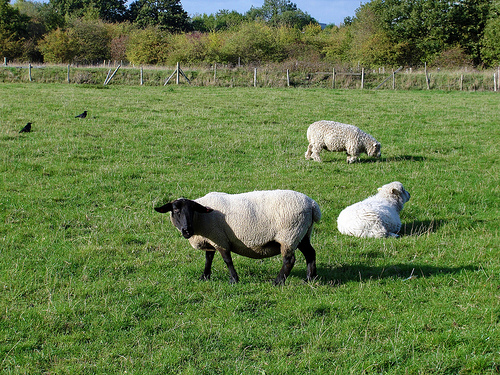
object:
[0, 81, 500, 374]
grass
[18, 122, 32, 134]
bird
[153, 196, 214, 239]
head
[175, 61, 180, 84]
poles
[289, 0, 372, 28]
sky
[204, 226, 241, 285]
legs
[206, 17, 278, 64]
shrub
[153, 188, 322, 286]
animal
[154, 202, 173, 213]
ears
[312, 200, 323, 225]
tail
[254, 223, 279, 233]
wool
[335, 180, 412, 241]
animal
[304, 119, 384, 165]
animal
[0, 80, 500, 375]
fenced area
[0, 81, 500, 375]
field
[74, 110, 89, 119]
birds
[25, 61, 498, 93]
fence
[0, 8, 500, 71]
wooded area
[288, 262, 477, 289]
shadow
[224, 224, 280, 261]
belly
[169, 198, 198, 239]
face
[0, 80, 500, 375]
ground